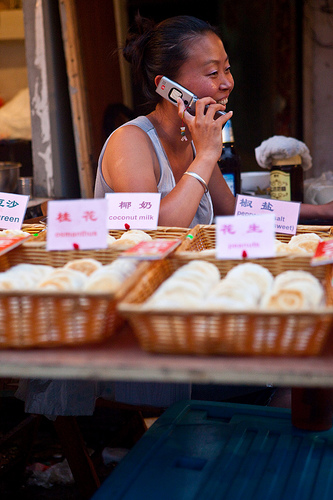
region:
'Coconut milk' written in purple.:
[104, 212, 158, 224]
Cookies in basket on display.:
[0, 221, 328, 365]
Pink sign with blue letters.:
[235, 191, 301, 234]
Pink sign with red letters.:
[47, 201, 107, 246]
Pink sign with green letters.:
[0, 190, 30, 228]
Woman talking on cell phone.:
[89, 17, 227, 224]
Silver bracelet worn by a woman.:
[178, 163, 210, 190]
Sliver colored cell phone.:
[155, 76, 230, 130]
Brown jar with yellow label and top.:
[267, 154, 303, 197]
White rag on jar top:
[253, 136, 312, 169]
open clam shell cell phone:
[147, 69, 230, 131]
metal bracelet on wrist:
[179, 164, 211, 196]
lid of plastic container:
[87, 391, 331, 494]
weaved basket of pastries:
[114, 252, 330, 361]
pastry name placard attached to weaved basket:
[209, 211, 279, 262]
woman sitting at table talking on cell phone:
[87, 11, 331, 225]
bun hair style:
[117, 9, 218, 108]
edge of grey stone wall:
[18, 2, 66, 206]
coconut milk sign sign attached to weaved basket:
[99, 185, 164, 233]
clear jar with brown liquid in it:
[263, 150, 308, 207]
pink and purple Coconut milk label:
[103, 191, 158, 229]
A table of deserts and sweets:
[0, 193, 328, 357]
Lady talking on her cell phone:
[90, 16, 326, 217]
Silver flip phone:
[150, 73, 224, 137]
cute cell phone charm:
[174, 102, 188, 142]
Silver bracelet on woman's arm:
[175, 166, 205, 191]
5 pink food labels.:
[0, 190, 310, 259]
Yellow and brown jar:
[265, 153, 305, 210]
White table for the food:
[2, 356, 331, 383]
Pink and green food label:
[0, 194, 30, 225]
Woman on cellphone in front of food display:
[14, 33, 317, 469]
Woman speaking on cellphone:
[89, 11, 250, 136]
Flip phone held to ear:
[150, 67, 235, 127]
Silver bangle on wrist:
[176, 165, 214, 195]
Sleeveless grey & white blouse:
[94, 114, 230, 225]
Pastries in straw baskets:
[2, 175, 330, 333]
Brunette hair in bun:
[110, 10, 217, 71]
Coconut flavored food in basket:
[98, 188, 170, 253]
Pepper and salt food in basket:
[233, 175, 327, 256]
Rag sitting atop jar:
[251, 129, 315, 199]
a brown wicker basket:
[117, 259, 328, 353]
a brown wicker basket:
[0, 240, 153, 347]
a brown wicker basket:
[170, 224, 332, 259]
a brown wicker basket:
[11, 223, 190, 257]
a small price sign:
[47, 198, 107, 249]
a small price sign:
[215, 214, 273, 256]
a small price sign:
[233, 192, 301, 234]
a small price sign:
[105, 189, 159, 228]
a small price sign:
[0, 188, 29, 227]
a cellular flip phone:
[154, 76, 228, 129]